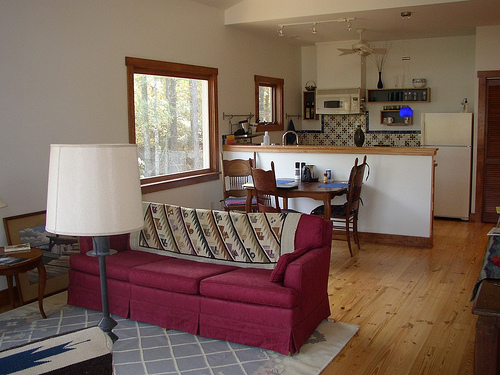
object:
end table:
[0, 244, 48, 319]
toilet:
[124, 54, 224, 195]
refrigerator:
[420, 112, 474, 221]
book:
[4, 243, 31, 253]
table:
[1, 241, 63, 319]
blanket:
[127, 200, 303, 270]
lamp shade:
[44, 143, 148, 236]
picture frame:
[0, 207, 78, 304]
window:
[125, 55, 224, 194]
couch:
[66, 201, 334, 356]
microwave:
[315, 87, 361, 115]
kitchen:
[214, 0, 499, 250]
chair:
[309, 155, 370, 258]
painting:
[0, 208, 82, 310]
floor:
[0, 216, 500, 375]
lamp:
[43, 142, 145, 345]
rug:
[0, 303, 362, 375]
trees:
[132, 77, 205, 180]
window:
[254, 73, 287, 132]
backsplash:
[290, 113, 422, 147]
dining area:
[218, 150, 373, 257]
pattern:
[136, 195, 287, 265]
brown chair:
[218, 151, 258, 214]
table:
[244, 181, 350, 221]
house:
[0, 0, 500, 375]